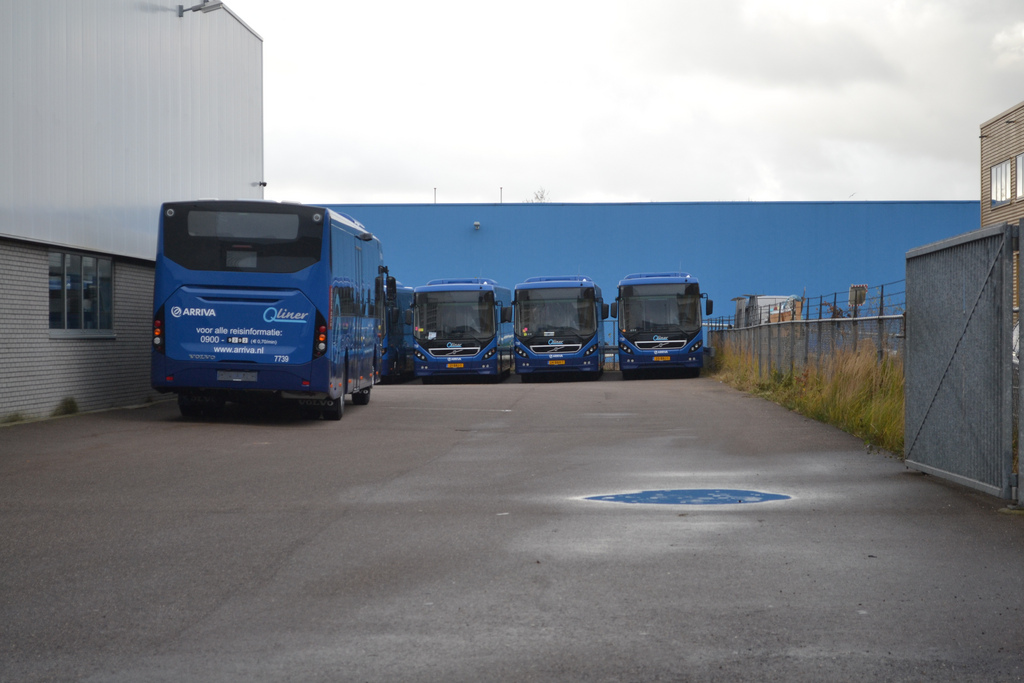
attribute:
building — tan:
[118, 60, 309, 171]